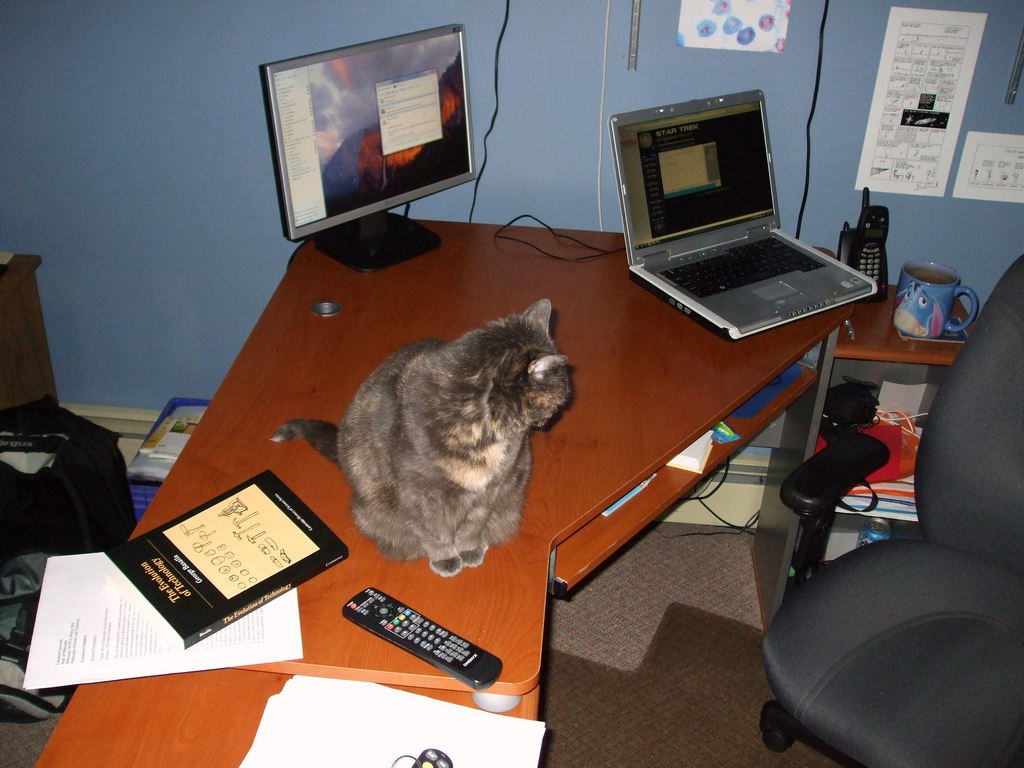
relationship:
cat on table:
[266, 298, 572, 579] [38, 211, 849, 754]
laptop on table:
[596, 69, 892, 338] [38, 211, 849, 754]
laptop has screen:
[596, 69, 892, 338] [620, 92, 780, 255]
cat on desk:
[266, 298, 572, 579] [34, 181, 977, 763]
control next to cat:
[336, 568, 514, 718] [266, 298, 572, 579]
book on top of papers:
[90, 466, 346, 652] [12, 554, 322, 710]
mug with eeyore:
[892, 261, 980, 339] [890, 280, 951, 339]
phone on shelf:
[835, 174, 900, 308] [715, 209, 986, 380]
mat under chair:
[535, 589, 825, 764] [759, 254, 1021, 764]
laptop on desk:
[596, 69, 892, 338] [38, 200, 860, 764]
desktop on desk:
[248, 32, 517, 283] [38, 200, 860, 764]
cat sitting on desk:
[266, 298, 572, 579] [38, 200, 860, 764]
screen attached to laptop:
[614, 111, 770, 245] [605, 72, 882, 347]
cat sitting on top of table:
[318, 292, 563, 574] [96, 197, 876, 764]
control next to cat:
[340, 587, 502, 693] [271, 299, 574, 576]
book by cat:
[99, 470, 349, 652] [271, 299, 574, 576]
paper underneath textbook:
[23, 550, 302, 695] [111, 475, 343, 648]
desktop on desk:
[258, 22, 479, 272] [38, 200, 860, 764]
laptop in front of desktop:
[607, 89, 878, 342] [258, 22, 479, 272]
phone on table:
[837, 187, 891, 303] [38, 211, 849, 754]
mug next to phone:
[893, 258, 976, 352] [856, 183, 895, 287]